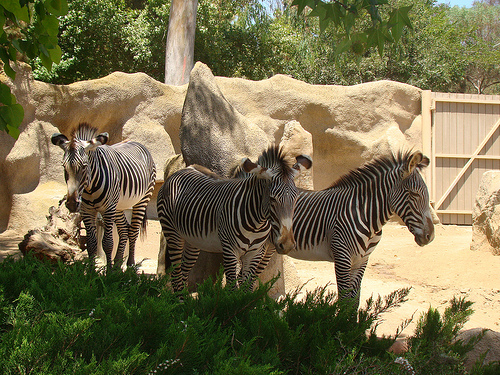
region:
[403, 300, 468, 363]
Green piece of shrubbery.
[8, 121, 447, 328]
Group of zebras together.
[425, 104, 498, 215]
Gate to the outside fence.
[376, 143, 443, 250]
Side of zebra head facing right.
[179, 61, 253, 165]
Big rock behind zebra.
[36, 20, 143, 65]
Green trees in the background.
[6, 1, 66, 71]
Small green leaves hanging down on the right.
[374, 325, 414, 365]
Small piece of trash on the floor.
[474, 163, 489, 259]
Big rock covered in dirt.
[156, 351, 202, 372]
Small pine cone in the trees.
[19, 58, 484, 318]
zebras that are outsid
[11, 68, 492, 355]
three zebras that are outside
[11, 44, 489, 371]
zebras in an area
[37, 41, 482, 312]
three zebras in an area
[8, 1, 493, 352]
zebras in a fenced in area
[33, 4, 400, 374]
three zebras in a fenced in area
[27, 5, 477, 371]
zebras that are fenced in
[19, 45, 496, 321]
three zebras fenced in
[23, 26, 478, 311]
a wall made of rock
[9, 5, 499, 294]
a big rock wall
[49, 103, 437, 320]
three zebras standing in a pen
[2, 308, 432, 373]
a green bush growing inside the pen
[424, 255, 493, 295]
tan dirt ground of the pen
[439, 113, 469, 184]
tan wood fence of the pen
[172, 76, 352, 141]
tan stone wall of the pen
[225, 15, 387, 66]
many trees growing outside the pen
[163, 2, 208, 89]
tan wood tree trunk outside the pen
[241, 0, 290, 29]
clear blue skies through the trees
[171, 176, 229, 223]
black and white stripes of the zebra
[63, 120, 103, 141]
black and white striped mane of the zebra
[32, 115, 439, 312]
a group of zebras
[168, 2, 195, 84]
a brown died tree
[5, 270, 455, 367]
a evergreen bush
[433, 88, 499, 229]
a tan wooden door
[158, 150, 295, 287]
black and white strips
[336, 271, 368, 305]
front leg of a zebra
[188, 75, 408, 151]
tan boulders behind zebras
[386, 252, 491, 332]
a sandy ground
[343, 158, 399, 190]
hair on the neck of a zebra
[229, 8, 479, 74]
green trees behind gate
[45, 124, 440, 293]
a group of zebras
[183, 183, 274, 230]
black white strips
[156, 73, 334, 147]
tan boulders behind zebra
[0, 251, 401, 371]
green leafy bushes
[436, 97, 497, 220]
a tan wooden gate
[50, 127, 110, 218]
a zebras black and white head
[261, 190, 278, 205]
a zebras right eye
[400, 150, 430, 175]
a zebras ears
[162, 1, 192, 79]
a gray tree trunk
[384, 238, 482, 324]
tan dirt on the ground